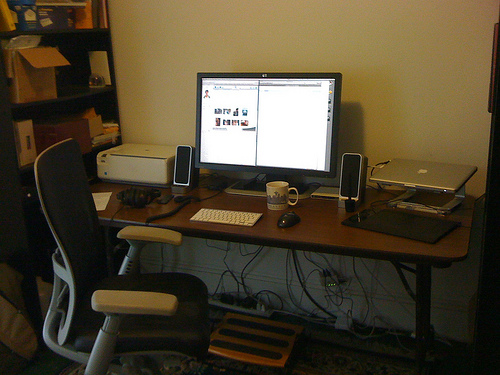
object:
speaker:
[336, 150, 370, 213]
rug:
[206, 310, 303, 369]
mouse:
[275, 208, 302, 229]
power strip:
[156, 242, 167, 274]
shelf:
[0, 26, 110, 41]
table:
[88, 172, 479, 374]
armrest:
[90, 288, 181, 318]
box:
[0, 46, 72, 106]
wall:
[106, 0, 500, 347]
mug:
[264, 178, 301, 212]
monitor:
[193, 70, 344, 202]